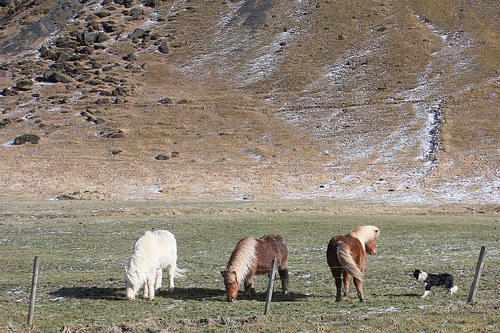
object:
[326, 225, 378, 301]
horse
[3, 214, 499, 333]
field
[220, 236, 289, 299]
horse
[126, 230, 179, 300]
horse